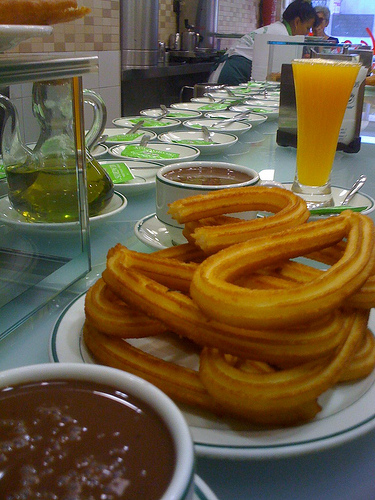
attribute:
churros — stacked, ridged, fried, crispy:
[82, 187, 373, 428]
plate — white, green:
[52, 261, 374, 461]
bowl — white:
[0, 363, 196, 499]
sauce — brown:
[2, 379, 177, 500]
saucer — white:
[194, 471, 218, 499]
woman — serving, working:
[207, 0, 322, 86]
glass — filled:
[291, 58, 361, 201]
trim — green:
[194, 412, 374, 451]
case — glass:
[0, 55, 100, 347]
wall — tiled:
[2, 1, 262, 148]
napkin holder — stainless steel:
[276, 63, 366, 154]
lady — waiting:
[312, 6, 339, 52]